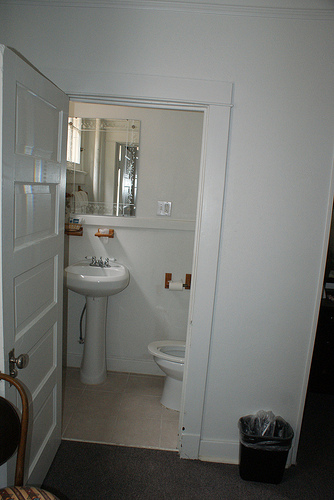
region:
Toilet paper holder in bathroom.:
[165, 271, 189, 292]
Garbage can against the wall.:
[233, 405, 293, 484]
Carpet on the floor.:
[78, 454, 205, 493]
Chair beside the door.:
[0, 364, 55, 497]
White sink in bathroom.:
[66, 254, 135, 390]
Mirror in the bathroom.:
[67, 115, 139, 217]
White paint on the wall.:
[246, 124, 294, 388]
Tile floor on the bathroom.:
[91, 400, 157, 438]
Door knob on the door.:
[13, 353, 31, 379]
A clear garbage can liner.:
[232, 408, 298, 453]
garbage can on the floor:
[238, 410, 286, 485]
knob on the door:
[9, 352, 38, 382]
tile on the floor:
[78, 418, 106, 441]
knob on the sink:
[108, 256, 117, 268]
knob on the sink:
[81, 255, 96, 267]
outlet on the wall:
[152, 201, 172, 216]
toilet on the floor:
[142, 334, 183, 411]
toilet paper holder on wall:
[160, 269, 191, 295]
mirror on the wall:
[63, 108, 130, 222]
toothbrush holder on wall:
[92, 225, 120, 238]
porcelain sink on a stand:
[62, 263, 126, 386]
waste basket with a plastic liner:
[237, 408, 295, 479]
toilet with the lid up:
[146, 339, 181, 411]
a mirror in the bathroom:
[64, 118, 140, 216]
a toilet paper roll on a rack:
[163, 271, 192, 290]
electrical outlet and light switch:
[155, 201, 172, 217]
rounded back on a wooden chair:
[0, 371, 31, 484]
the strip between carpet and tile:
[61, 435, 180, 451]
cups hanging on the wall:
[95, 227, 115, 244]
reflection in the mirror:
[66, 117, 140, 215]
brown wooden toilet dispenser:
[163, 272, 191, 291]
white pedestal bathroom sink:
[63, 263, 128, 386]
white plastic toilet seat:
[146, 338, 184, 361]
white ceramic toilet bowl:
[157, 345, 185, 412]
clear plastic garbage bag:
[239, 410, 295, 449]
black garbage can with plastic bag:
[239, 418, 294, 483]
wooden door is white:
[0, 42, 69, 487]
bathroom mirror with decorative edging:
[60, 117, 140, 216]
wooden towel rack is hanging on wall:
[62, 186, 89, 200]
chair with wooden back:
[0, 373, 55, 497]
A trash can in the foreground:
[229, 405, 297, 488]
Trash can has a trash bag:
[228, 404, 296, 459]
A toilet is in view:
[141, 328, 197, 422]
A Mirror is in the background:
[69, 108, 145, 225]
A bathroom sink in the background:
[66, 249, 138, 391]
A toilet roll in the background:
[162, 268, 197, 294]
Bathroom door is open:
[1, 35, 199, 491]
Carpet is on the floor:
[28, 432, 329, 496]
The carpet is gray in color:
[24, 419, 330, 495]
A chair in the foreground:
[0, 368, 66, 497]